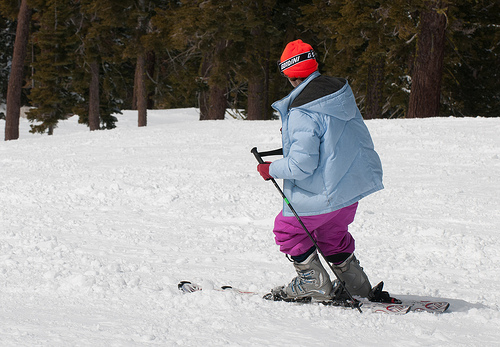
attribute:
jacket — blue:
[268, 62, 387, 220]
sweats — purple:
[273, 200, 360, 262]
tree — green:
[23, 0, 87, 136]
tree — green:
[66, 0, 135, 130]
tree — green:
[163, 2, 271, 119]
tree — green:
[317, 3, 497, 123]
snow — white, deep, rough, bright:
[0, 103, 500, 343]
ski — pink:
[175, 278, 416, 316]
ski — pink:
[216, 280, 450, 315]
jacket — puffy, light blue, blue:
[268, 71, 385, 215]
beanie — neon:
[276, 38, 321, 81]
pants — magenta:
[270, 197, 362, 264]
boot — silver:
[260, 249, 333, 303]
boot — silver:
[324, 254, 384, 299]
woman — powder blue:
[254, 35, 384, 302]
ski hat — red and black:
[276, 38, 319, 78]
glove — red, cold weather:
[256, 156, 272, 182]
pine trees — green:
[0, 1, 484, 110]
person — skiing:
[243, 33, 400, 312]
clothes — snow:
[256, 9, 423, 331]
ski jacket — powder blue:
[264, 70, 382, 217]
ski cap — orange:
[276, 37, 317, 76]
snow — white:
[9, 116, 454, 343]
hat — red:
[278, 40, 318, 78]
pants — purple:
[271, 201, 361, 260]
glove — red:
[257, 157, 276, 183]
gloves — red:
[254, 160, 274, 179]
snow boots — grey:
[275, 257, 368, 305]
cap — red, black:
[278, 36, 315, 78]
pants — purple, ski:
[298, 207, 361, 264]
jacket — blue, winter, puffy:
[277, 90, 365, 204]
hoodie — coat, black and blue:
[297, 77, 357, 123]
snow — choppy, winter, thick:
[150, 302, 303, 331]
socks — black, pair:
[296, 243, 352, 264]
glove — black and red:
[250, 154, 272, 186]